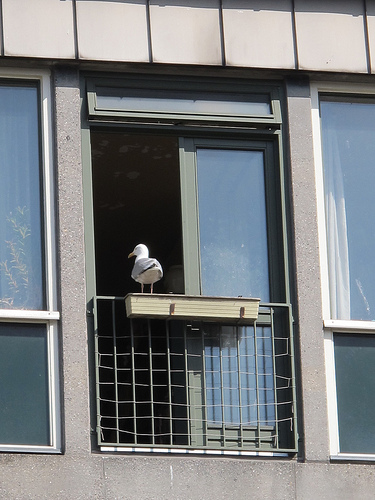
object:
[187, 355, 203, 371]
hole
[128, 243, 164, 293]
beak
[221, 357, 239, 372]
hole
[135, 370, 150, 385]
hole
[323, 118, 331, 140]
ground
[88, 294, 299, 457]
fence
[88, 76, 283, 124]
small window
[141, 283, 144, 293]
leg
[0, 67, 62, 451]
window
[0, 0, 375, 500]
apartment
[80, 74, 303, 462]
window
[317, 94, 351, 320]
curtain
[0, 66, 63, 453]
frame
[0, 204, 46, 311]
plant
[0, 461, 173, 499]
mark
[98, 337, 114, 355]
hole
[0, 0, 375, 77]
tile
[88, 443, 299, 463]
windowsill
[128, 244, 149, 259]
head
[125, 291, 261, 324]
block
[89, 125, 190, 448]
interior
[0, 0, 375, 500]
building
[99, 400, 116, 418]
hole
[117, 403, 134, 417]
hole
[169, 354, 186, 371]
hole